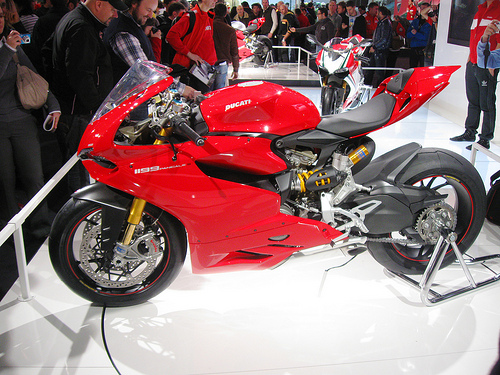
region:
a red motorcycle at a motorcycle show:
[11, 5, 489, 332]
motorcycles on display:
[232, 24, 380, 128]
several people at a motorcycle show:
[251, 5, 430, 65]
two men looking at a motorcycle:
[45, 0, 190, 229]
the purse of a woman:
[11, 59, 50, 119]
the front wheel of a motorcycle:
[43, 193, 192, 314]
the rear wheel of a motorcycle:
[363, 143, 485, 281]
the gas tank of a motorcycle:
[193, 70, 325, 139]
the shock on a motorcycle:
[118, 193, 148, 250]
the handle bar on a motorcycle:
[173, 111, 210, 151]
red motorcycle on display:
[47, 28, 489, 307]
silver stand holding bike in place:
[383, 223, 499, 307]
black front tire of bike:
[45, 198, 188, 312]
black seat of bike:
[316, 83, 404, 139]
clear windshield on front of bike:
[88, 57, 170, 125]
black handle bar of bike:
[162, 113, 205, 160]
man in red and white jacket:
[451, 0, 498, 149]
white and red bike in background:
[301, 30, 372, 119]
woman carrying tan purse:
[11, 48, 52, 112]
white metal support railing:
[14, 233, 36, 300]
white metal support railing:
[87, 172, 97, 185]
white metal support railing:
[296, 48, 305, 67]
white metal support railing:
[303, 53, 313, 71]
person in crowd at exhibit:
[51, 3, 121, 190]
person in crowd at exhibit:
[369, 5, 391, 65]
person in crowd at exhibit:
[406, 10, 431, 57]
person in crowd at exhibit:
[248, 3, 261, 17]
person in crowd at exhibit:
[261, 0, 276, 37]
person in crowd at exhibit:
[276, 3, 296, 38]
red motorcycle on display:
[60, 47, 479, 296]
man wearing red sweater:
[174, 1, 234, 76]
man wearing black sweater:
[44, 0, 116, 146]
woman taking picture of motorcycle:
[3, 15, 57, 203]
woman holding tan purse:
[0, 13, 65, 188]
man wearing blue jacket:
[404, 8, 434, 62]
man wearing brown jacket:
[212, 5, 249, 90]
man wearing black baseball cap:
[55, 3, 122, 105]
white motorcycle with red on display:
[300, 28, 381, 111]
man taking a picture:
[286, 8, 338, 64]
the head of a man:
[53, 3, 134, 40]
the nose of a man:
[96, 6, 128, 30]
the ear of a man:
[83, 2, 110, 26]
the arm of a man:
[53, 0, 113, 112]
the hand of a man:
[177, 45, 209, 67]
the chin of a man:
[129, 11, 155, 30]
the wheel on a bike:
[48, 193, 202, 329]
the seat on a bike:
[277, 40, 469, 175]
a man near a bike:
[42, 15, 223, 227]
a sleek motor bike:
[49, 51, 474, 293]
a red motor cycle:
[47, 45, 472, 300]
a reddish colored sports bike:
[46, 45, 491, 296]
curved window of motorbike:
[83, 59, 171, 151]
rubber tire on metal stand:
[369, 146, 497, 306]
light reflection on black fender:
[72, 183, 132, 212]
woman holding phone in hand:
[0, 7, 60, 194]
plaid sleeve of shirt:
[112, 31, 147, 65]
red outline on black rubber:
[49, 190, 188, 304]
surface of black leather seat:
[316, 92, 396, 137]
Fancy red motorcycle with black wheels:
[35, 44, 498, 316]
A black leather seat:
[305, 86, 402, 143]